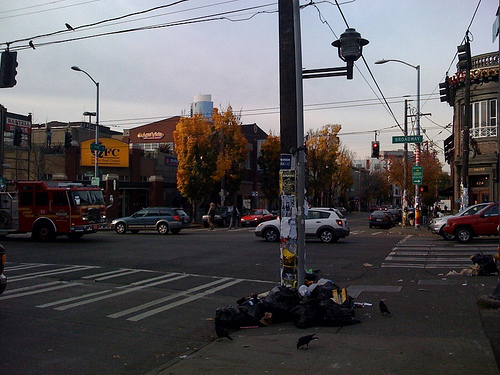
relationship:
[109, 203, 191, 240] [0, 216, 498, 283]
car on road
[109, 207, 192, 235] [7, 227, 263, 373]
car in road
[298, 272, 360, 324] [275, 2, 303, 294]
man sitting near pole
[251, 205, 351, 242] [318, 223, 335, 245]
car has wheel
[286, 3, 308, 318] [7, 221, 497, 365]
pole in road